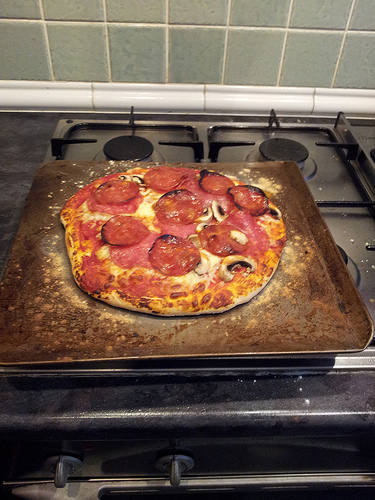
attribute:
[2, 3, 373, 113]
wall — burned, short, grey, white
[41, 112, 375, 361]
stove — black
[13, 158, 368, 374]
tray — brown, dusty, black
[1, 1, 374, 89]
tile — gray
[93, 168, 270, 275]
toppings — large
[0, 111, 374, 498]
stove — gray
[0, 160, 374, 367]
pan — dirty, pizza pan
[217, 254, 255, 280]
mushroom — sliced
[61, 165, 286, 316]
pizza — cooked, done, burnt, yellow, red, orange, small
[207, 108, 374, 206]
burner — black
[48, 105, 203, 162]
burner — black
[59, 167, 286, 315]
crust — toasted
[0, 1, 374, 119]
tiles — green gray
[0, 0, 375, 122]
backsplash — green gray